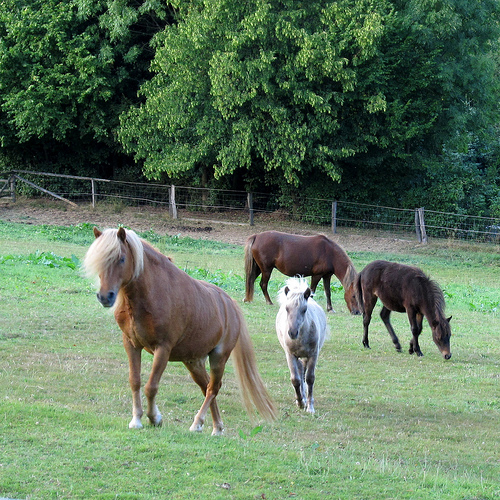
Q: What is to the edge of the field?
A: Wire fence.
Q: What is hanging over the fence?
A: Limbs.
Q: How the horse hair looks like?
A: Good.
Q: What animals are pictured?
A: Horses.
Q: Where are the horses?
A: Field.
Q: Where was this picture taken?
A: Farm.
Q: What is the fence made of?
A: Wire.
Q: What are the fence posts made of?
A: Wood.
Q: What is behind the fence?
A: Trees.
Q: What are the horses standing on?
A: Grass.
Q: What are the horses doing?
A: Grazing.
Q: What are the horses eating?
A: Grass.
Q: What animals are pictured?
A: Horses.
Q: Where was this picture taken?
A: A farm.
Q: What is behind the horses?
A: Fence.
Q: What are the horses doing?
A: Grazing.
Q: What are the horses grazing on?
A: Grass.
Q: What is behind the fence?
A: Trees.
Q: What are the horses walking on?
A: Grass.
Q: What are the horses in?
A: A field.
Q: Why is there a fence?
A: To keep the horses in.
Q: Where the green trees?
A: Behind the fence.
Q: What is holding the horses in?
A: Fence.